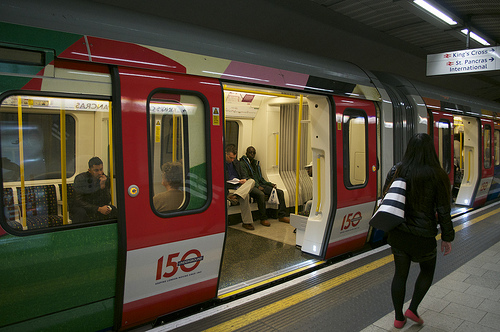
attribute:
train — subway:
[7, 28, 475, 302]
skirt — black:
[387, 226, 442, 266]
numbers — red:
[125, 225, 232, 305]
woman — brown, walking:
[381, 133, 456, 329]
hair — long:
[394, 131, 442, 191]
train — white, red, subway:
[21, 27, 487, 323]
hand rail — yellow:
[292, 99, 305, 216]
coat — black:
[374, 157, 459, 254]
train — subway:
[0, 20, 499, 330]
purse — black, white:
[368, 165, 410, 250]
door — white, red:
[114, 75, 227, 307]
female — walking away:
[362, 132, 454, 329]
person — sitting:
[221, 138, 256, 235]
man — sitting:
[228, 147, 296, 204]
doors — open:
[112, 63, 377, 325]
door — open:
[427, 108, 495, 208]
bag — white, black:
[365, 163, 412, 229]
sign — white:
[420, 43, 497, 79]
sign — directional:
[418, 46, 499, 73]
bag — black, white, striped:
[363, 172, 410, 236]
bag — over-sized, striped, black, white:
[374, 165, 407, 241]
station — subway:
[359, 14, 484, 329]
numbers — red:
[161, 257, 198, 276]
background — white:
[126, 243, 222, 292]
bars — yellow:
[287, 94, 307, 244]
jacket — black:
[384, 158, 458, 235]